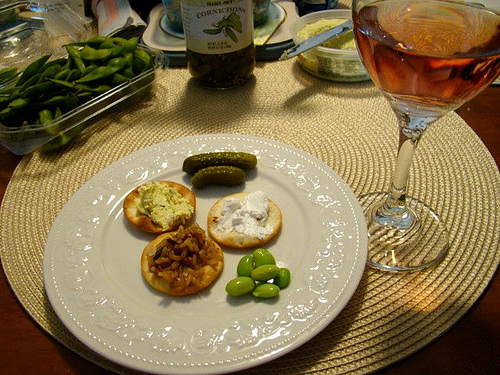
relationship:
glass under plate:
[354, 0, 500, 271] [26, 115, 384, 350]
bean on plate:
[250, 283, 282, 304] [289, 172, 382, 278]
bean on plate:
[225, 276, 255, 297] [289, 172, 382, 278]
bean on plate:
[249, 263, 285, 284] [289, 172, 382, 278]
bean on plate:
[274, 260, 294, 292] [289, 172, 382, 278]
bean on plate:
[243, 253, 257, 282] [289, 172, 382, 278]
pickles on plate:
[182, 152, 258, 176] [37, 129, 371, 373]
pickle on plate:
[188, 164, 254, 194] [37, 129, 371, 373]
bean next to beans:
[250, 264, 279, 281] [223, 247, 290, 298]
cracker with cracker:
[206, 191, 288, 251] [207, 190, 282, 248]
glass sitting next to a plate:
[347, 52, 458, 309] [96, 98, 413, 355]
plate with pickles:
[21, 128, 334, 349] [168, 141, 352, 247]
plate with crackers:
[21, 128, 334, 349] [121, 189, 287, 297]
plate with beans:
[21, 128, 334, 349] [219, 245, 295, 303]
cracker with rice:
[139, 231, 219, 292] [158, 234, 203, 286]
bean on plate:
[252, 283, 280, 297] [37, 129, 371, 373]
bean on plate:
[223, 275, 253, 296] [37, 129, 371, 373]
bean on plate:
[250, 264, 279, 281] [37, 129, 371, 373]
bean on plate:
[252, 245, 274, 268] [37, 129, 371, 373]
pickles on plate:
[180, 150, 258, 186] [37, 129, 371, 373]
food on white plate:
[100, 147, 322, 314] [31, 123, 405, 370]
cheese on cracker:
[220, 192, 277, 239] [204, 187, 296, 249]